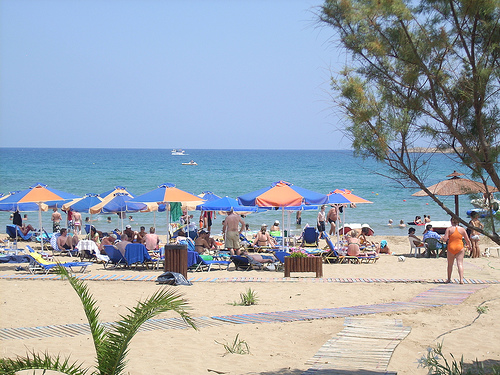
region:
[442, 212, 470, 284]
The lady in the orange bathing suit.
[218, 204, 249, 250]
The man standing up in the beige shorts.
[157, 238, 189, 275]
The wooden garbage can.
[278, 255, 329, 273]
The wooden plant stand to the right of the wooden trash can.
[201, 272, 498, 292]
The make shift sidewalk the lady in the orange bathing suit is wearing.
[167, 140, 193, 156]
The white boat in the distance.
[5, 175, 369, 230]
The orange and blue umbrellas.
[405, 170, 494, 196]
The wooden umbrella on the right.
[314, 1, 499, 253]
The tree on the right.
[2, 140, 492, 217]
The water in the distance.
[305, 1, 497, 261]
Large green tree on the right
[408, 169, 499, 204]
Brown shade umbrella to the right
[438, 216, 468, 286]
Woman to the right in an orange swimsuit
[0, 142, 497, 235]
Ocean behind the people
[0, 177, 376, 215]
Group of orange and blue shade umbrellas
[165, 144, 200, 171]
Two boats out on the water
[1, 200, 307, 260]
Group of people sitting under the umbrella's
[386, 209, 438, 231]
people in the water to the right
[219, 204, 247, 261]
Man standing with beige shorts and no shirt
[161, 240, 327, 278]
brown containers behind the people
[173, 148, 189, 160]
The boat in the background is white.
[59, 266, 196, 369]
The plant in the forefront is green.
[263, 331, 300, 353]
The sand in the forefront is light in color.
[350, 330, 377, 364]
The walkway is made of wood.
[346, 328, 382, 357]
The walkway is light in color.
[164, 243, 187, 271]
The garbage container is brown.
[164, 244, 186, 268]
The garbage container is made of wood.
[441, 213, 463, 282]
The woman is wearing a orange bathing suite.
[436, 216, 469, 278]
The womans hair is brown.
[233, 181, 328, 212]
The umbrella is orange and blue.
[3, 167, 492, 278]
people at the beach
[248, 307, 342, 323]
mat for walking across sand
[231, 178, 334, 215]
tent to one of several tables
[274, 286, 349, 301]
sand on the beach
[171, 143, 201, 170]
boat in the water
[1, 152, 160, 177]
body of water in beach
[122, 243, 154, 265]
beach towel on a chair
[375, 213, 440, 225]
people in the water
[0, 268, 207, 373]
plant on the beach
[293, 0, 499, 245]
tree on the beach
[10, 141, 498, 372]
a nice friendly beach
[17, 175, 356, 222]
beach umbrellas being used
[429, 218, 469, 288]
a person walking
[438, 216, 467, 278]
a person in their bathing suit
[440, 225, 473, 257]
the bathing suit is orange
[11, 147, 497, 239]
the wide seawater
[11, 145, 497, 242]
the water is a nice blue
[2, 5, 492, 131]
the clear soothing sky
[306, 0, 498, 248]
a tree on the beach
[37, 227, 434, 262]
people sitting down